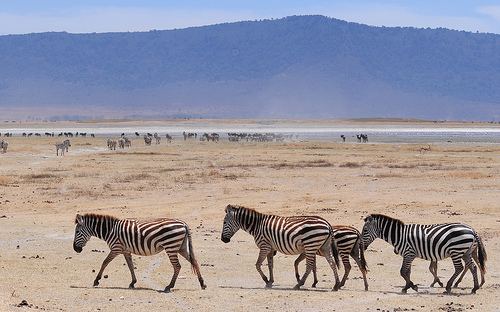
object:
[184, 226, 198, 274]
tail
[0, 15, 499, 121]
mountain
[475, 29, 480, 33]
trees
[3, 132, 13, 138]
animal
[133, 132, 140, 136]
animal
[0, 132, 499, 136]
water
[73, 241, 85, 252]
muzzle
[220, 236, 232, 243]
muzzle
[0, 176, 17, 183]
weeds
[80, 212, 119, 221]
mane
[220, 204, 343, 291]
zebras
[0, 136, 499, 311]
field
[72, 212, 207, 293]
zebra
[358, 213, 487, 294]
zebra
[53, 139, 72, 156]
zebra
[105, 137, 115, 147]
zebra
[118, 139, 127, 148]
zebra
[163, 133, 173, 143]
zebra